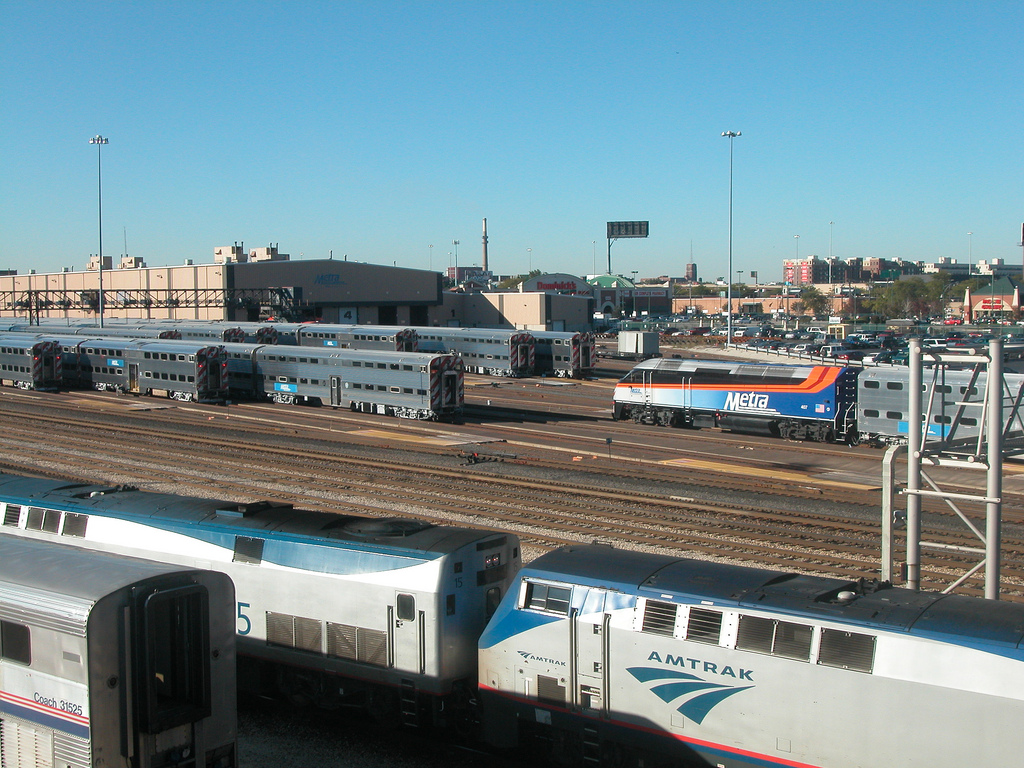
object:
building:
[2, 260, 443, 333]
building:
[444, 292, 593, 332]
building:
[783, 258, 807, 286]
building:
[945, 286, 1024, 327]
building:
[517, 272, 672, 319]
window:
[733, 613, 816, 670]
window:
[816, 626, 877, 674]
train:
[2, 470, 522, 748]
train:
[254, 343, 465, 422]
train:
[78, 340, 229, 404]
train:
[3, 330, 64, 394]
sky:
[6, 5, 1022, 240]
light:
[721, 130, 742, 138]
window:
[265, 610, 322, 654]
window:
[523, 581, 574, 619]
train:
[5, 479, 1020, 765]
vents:
[640, 599, 683, 611]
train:
[476, 536, 1024, 765]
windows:
[390, 386, 400, 393]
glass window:
[523, 581, 573, 616]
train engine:
[477, 540, 1024, 763]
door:
[330, 377, 342, 406]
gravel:
[561, 534, 585, 539]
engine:
[611, 357, 857, 446]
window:
[618, 369, 642, 385]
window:
[863, 380, 879, 389]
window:
[863, 409, 879, 419]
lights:
[88, 134, 109, 145]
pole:
[98, 144, 104, 331]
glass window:
[232, 536, 266, 567]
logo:
[624, 667, 755, 726]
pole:
[607, 237, 611, 275]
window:
[377, 385, 387, 392]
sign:
[607, 220, 650, 238]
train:
[611, 358, 1020, 459]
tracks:
[0, 383, 889, 584]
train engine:
[0, 532, 241, 766]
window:
[735, 365, 768, 376]